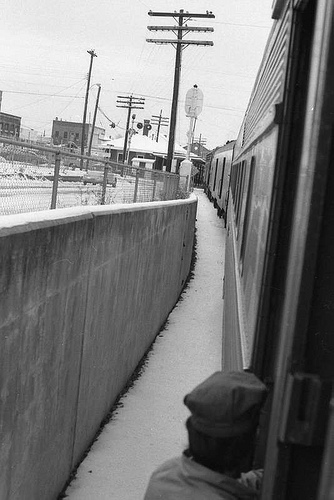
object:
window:
[231, 164, 237, 205]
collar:
[180, 447, 261, 498]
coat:
[143, 448, 262, 500]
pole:
[179, 85, 202, 199]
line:
[143, 52, 150, 64]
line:
[137, 48, 143, 54]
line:
[183, 56, 190, 66]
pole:
[164, 42, 181, 170]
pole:
[120, 108, 131, 178]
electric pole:
[145, 6, 214, 172]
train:
[201, 0, 330, 497]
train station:
[3, 126, 205, 492]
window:
[217, 158, 227, 198]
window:
[212, 158, 218, 190]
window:
[207, 158, 211, 186]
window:
[239, 156, 255, 264]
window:
[232, 161, 242, 213]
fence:
[0, 135, 189, 213]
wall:
[0, 196, 197, 500]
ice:
[110, 429, 151, 457]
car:
[82, 161, 117, 187]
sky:
[0, 2, 85, 86]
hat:
[182, 365, 273, 422]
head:
[185, 367, 262, 467]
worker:
[141, 369, 269, 500]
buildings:
[51, 117, 104, 150]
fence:
[0, 139, 72, 209]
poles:
[85, 84, 101, 172]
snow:
[145, 199, 173, 205]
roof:
[99, 134, 203, 161]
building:
[102, 132, 205, 183]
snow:
[106, 134, 176, 152]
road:
[0, 176, 165, 217]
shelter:
[149, 155, 199, 180]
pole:
[185, 116, 196, 159]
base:
[179, 159, 194, 177]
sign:
[185, 86, 205, 116]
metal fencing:
[3, 149, 184, 203]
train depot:
[97, 118, 203, 186]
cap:
[182, 368, 272, 441]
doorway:
[234, 0, 315, 495]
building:
[130, 156, 154, 181]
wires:
[1, 90, 50, 97]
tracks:
[202, 187, 230, 256]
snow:
[227, 191, 239, 239]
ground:
[150, 349, 199, 367]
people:
[142, 367, 270, 500]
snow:
[138, 251, 222, 364]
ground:
[186, 302, 217, 351]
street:
[22, 172, 91, 201]